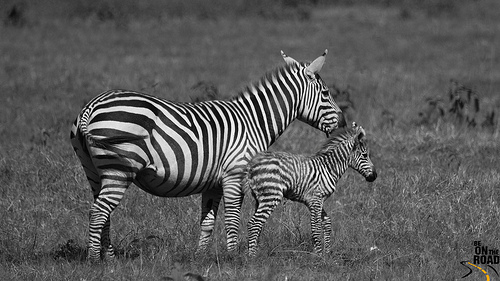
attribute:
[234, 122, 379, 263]
zebra — striped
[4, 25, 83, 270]
grass — tall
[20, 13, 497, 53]
grass — tall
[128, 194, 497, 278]
grass — tall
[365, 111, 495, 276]
grass — tall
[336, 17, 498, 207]
grass — tall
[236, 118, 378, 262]
baby zebra — black and white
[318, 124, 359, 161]
fur — fluffy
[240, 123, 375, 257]
zebra — striped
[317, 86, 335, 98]
eye — black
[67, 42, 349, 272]
zebra — striped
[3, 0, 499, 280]
grass — beautiful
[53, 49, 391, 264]
zebra — striped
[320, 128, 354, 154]
mane — black and white, fluffy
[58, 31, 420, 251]
zebra — striped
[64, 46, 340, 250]
zebra — striped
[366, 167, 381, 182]
nose — black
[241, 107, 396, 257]
zebra — small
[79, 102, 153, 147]
tail — wagging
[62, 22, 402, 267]
zebra — black, white